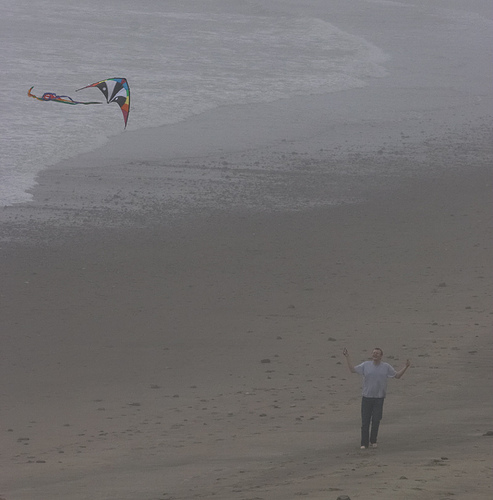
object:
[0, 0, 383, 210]
sea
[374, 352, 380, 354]
eye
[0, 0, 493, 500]
shore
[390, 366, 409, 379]
arm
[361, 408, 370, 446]
leg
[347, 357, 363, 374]
arm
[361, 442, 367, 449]
foot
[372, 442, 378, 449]
foot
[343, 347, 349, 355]
hand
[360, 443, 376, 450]
shoes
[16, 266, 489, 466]
footprints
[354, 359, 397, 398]
shirt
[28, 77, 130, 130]
kite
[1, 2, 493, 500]
beach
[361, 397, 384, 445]
man's pants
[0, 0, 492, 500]
sand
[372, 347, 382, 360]
head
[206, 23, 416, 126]
air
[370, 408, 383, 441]
leg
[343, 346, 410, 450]
man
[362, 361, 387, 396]
body